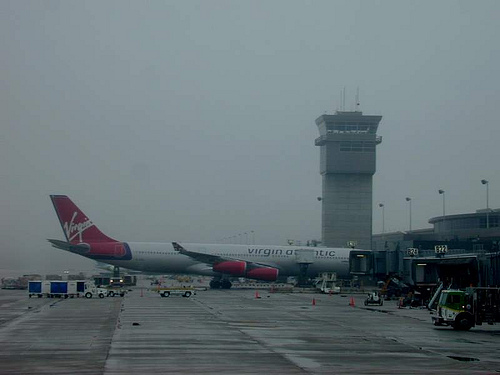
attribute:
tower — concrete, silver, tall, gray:
[315, 83, 385, 248]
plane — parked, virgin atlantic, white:
[46, 192, 372, 289]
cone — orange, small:
[348, 294, 358, 308]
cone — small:
[312, 298, 316, 306]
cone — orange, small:
[254, 290, 261, 299]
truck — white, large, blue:
[27, 277, 108, 299]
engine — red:
[214, 259, 277, 280]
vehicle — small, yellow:
[155, 283, 198, 300]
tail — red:
[48, 192, 128, 264]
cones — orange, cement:
[253, 290, 356, 307]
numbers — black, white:
[435, 245, 449, 254]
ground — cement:
[1, 277, 499, 375]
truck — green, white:
[434, 286, 499, 331]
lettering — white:
[62, 211, 94, 243]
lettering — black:
[248, 246, 337, 257]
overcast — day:
[1, 0, 499, 277]